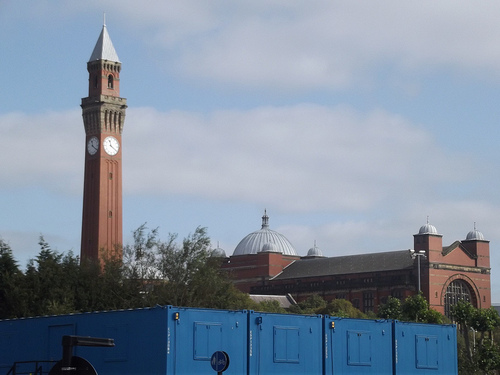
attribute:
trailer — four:
[14, 307, 256, 374]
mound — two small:
[462, 222, 486, 241]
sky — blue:
[0, 2, 499, 261]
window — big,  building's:
[104, 67, 113, 93]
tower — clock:
[58, 35, 144, 291]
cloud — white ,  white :
[3, 105, 488, 211]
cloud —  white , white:
[114, 2, 499, 91]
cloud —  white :
[295, 201, 499, 246]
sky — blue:
[247, 104, 439, 252]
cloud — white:
[275, 205, 493, 254]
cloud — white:
[283, 32, 368, 82]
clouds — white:
[203, 55, 285, 96]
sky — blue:
[145, 81, 232, 115]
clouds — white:
[247, 112, 304, 163]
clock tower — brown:
[64, 24, 156, 271]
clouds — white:
[1, 107, 496, 252]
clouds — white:
[98, 2, 498, 92]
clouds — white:
[236, 80, 417, 215]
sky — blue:
[150, 45, 450, 199]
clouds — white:
[182, 115, 443, 192]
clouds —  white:
[11, 6, 497, 103]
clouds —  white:
[7, 66, 477, 228]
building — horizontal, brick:
[180, 201, 495, 324]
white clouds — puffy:
[185, 0, 498, 100]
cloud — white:
[164, 2, 401, 90]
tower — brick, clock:
[76, 7, 131, 295]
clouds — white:
[1, 100, 485, 208]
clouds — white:
[141, 0, 498, 92]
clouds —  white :
[6, 28, 51, 90]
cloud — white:
[173, 37, 338, 93]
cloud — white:
[117, 107, 441, 187]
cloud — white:
[160, 0, 499, 91]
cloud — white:
[5, 108, 82, 170]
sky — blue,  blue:
[14, 10, 488, 304]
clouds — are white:
[3, 105, 498, 231]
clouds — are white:
[3, 2, 498, 94]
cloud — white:
[289, 205, 497, 314]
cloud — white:
[0, 94, 432, 199]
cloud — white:
[55, 0, 494, 90]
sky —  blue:
[130, 3, 498, 204]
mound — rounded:
[228, 220, 306, 262]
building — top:
[198, 207, 498, 329]